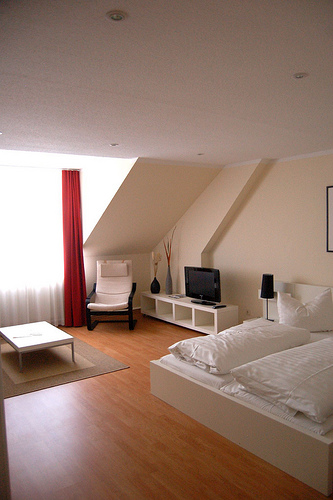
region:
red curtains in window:
[56, 177, 85, 215]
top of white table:
[11, 322, 57, 341]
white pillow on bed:
[279, 294, 329, 323]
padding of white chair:
[99, 293, 122, 306]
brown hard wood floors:
[96, 421, 138, 460]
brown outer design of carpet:
[69, 371, 86, 379]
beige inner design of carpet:
[42, 363, 61, 371]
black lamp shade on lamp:
[258, 270, 275, 302]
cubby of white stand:
[170, 301, 198, 327]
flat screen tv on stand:
[179, 264, 225, 304]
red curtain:
[57, 158, 105, 335]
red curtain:
[50, 203, 92, 307]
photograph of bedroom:
[55, 188, 315, 479]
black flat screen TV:
[185, 258, 226, 324]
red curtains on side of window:
[66, 162, 89, 329]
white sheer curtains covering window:
[6, 167, 66, 326]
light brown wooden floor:
[66, 408, 122, 490]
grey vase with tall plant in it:
[162, 230, 182, 297]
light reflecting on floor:
[23, 372, 89, 476]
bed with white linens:
[213, 280, 331, 403]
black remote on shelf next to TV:
[211, 299, 230, 313]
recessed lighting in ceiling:
[67, 5, 330, 108]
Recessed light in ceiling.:
[105, 8, 130, 21]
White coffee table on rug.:
[2, 320, 89, 385]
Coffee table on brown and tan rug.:
[4, 320, 97, 380]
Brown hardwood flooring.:
[60, 389, 150, 438]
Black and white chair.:
[86, 258, 139, 331]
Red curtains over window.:
[61, 166, 86, 326]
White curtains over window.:
[2, 167, 61, 319]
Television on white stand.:
[182, 265, 227, 323]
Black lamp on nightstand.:
[259, 272, 277, 325]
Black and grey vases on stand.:
[149, 233, 175, 297]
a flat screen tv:
[175, 263, 228, 303]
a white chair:
[65, 254, 140, 344]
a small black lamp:
[251, 269, 280, 339]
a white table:
[143, 284, 234, 321]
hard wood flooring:
[60, 406, 199, 474]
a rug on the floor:
[34, 334, 132, 405]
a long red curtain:
[55, 163, 84, 338]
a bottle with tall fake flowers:
[162, 227, 175, 300]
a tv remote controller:
[211, 294, 230, 316]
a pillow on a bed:
[265, 280, 332, 343]